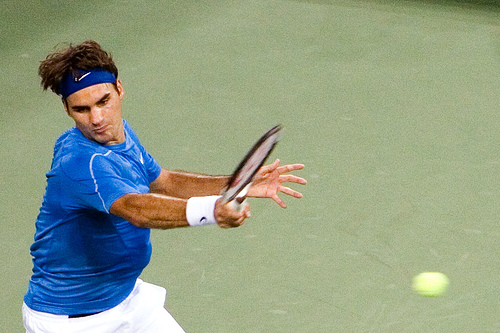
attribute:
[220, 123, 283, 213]
tennis racket — black, white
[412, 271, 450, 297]
tennis ball — green, small, flying, yellow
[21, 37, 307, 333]
man — playing tennis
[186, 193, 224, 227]
wrist guard — white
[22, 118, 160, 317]
t-shirt — blue, short-sleeved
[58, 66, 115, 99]
headband — dark blue, blue, nike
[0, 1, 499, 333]
tennis court — green, light green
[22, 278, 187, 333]
shorts — white, athletic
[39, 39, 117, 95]
hair — brown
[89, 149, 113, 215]
stripe — white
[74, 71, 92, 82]
swoosh — white